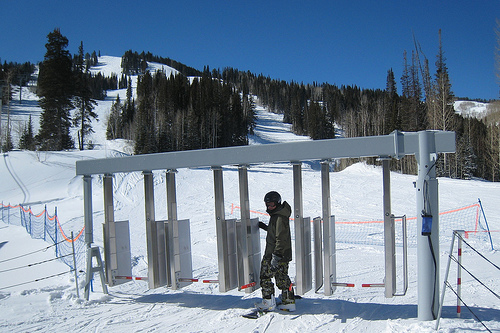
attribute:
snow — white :
[58, 275, 213, 330]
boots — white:
[229, 251, 357, 319]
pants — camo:
[255, 260, 305, 302]